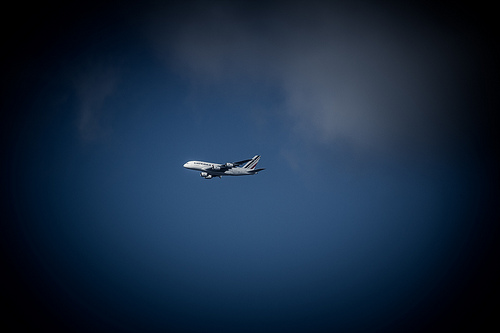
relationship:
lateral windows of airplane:
[191, 160, 213, 164] [182, 156, 264, 179]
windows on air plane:
[170, 153, 215, 170] [222, 159, 292, 205]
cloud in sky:
[0, 0, 500, 333] [3, 2, 496, 329]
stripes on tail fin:
[242, 156, 260, 171] [232, 152, 272, 171]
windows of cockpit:
[193, 162, 204, 166] [179, 156, 197, 171]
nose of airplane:
[183, 161, 191, 169] [165, 141, 275, 188]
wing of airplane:
[220, 156, 253, 168] [177, 151, 277, 183]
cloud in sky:
[155, 17, 442, 152] [3, 2, 496, 329]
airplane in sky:
[180, 155, 267, 180] [3, 2, 496, 329]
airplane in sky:
[182, 154, 267, 179] [342, 75, 427, 219]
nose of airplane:
[181, 159, 192, 169] [181, 150, 266, 180]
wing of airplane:
[243, 154, 261, 170] [177, 153, 271, 184]